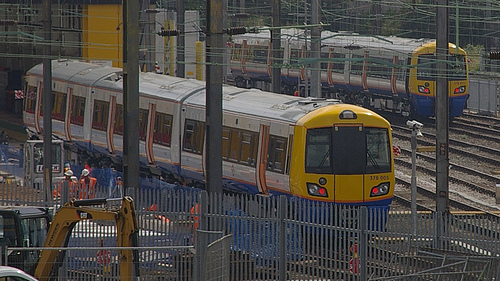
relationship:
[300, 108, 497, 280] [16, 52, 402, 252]
tracks of train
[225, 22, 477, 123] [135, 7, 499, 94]
train in background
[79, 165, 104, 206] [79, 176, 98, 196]
men wearing vest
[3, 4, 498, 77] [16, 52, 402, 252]
electric wires above train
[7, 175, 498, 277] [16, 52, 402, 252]
fence near train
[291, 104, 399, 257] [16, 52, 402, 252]
front of train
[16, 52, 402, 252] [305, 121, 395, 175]
train has windshield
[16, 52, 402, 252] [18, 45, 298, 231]
train has grey cars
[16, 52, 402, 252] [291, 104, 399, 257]
train has yellow front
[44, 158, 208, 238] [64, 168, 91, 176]
people wear hard hats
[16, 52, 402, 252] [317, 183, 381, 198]
train has red headlights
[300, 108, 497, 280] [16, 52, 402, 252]
tracks for train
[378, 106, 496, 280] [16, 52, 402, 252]
track for train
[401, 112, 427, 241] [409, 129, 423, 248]
cameras on pole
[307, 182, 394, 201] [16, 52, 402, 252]
headlights on train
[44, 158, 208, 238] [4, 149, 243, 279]
people working at trainyard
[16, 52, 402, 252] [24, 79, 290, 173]
train has windows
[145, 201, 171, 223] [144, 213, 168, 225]
worker wearing safety vest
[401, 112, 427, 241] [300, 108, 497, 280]
camera on tracks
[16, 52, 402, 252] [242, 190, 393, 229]
train blue on bottom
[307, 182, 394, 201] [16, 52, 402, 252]
lights on front of train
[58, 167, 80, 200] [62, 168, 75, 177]
worker wears white helmet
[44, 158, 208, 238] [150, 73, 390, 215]
people near train